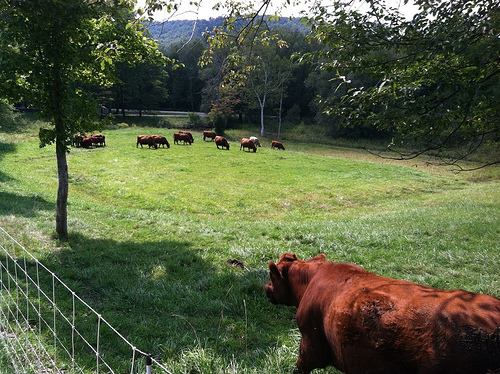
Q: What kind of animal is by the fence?
A: A cow.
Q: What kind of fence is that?
A: A metal fence.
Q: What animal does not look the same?
A: The light colored cow.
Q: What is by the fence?
A: A small tree.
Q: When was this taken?
A: During the day time.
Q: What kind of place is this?
A: A small green field.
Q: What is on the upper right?
A: Tree branches.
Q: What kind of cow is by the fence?
A: A dark brown cow.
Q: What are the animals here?
A: Cows.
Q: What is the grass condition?
A: Lush.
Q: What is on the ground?
A: Shadow.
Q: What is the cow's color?
A: Brown.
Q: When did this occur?
A: During the day time.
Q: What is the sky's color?
A: White.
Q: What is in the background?
A: Hills.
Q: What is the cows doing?
A: Grazing.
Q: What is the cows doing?
A: Standing.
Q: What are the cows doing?
A: Grazing.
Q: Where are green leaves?
A: On the trees.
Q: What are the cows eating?
A: Grass.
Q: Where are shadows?
A: On the grass.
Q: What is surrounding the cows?
A: A fence.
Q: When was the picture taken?
A: During the daytime.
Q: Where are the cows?
A: On a grassy field.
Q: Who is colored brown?
A: The cows.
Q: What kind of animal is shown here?
A: Cows.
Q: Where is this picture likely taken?
A: A farm.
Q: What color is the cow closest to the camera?
A: Brown.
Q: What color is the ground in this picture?
A: Green.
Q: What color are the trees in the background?
A: Green.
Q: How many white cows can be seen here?
A: One.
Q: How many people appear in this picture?
A: Zero.